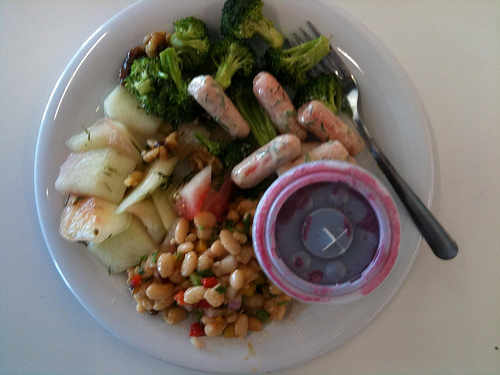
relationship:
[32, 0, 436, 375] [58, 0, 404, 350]
plate has a meal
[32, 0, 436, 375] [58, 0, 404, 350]
plate has food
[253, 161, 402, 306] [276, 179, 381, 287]
container has sauce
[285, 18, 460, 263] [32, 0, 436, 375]
fork on plate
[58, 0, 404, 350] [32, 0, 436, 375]
meal on a plate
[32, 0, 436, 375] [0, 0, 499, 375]
plate on surface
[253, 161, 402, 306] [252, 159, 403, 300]
container has a lid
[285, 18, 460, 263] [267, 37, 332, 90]
fork under broccoli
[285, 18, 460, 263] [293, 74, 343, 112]
fork under broccoli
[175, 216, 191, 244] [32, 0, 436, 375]
bean on plate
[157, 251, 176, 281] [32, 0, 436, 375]
bean on plate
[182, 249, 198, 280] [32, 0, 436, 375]
bean on plate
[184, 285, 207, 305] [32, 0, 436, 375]
bean on plate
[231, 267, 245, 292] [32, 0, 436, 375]
bean on plate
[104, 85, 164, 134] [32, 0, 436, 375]
potato on plate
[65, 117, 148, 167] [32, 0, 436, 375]
potato on plate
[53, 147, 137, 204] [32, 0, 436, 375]
potato on plate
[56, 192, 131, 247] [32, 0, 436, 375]
potato on plate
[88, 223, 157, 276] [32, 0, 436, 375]
potato on plate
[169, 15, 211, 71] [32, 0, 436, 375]
broccoli on plate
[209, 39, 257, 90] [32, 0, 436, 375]
broccoli on plate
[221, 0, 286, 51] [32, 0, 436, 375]
broccoli on plate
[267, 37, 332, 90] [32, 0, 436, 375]
broccoli on plate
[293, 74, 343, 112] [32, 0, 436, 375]
broccoli on plate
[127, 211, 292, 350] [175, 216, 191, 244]
salad has a bean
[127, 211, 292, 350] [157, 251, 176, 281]
salad has a bean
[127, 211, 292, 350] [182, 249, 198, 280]
salad has a bean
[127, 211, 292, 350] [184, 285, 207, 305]
salad has a bean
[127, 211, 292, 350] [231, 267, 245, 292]
salad has a bean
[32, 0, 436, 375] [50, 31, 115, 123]
plate has a reflection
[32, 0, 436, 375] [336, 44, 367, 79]
plate has a reflection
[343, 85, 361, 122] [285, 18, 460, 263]
reflection on fork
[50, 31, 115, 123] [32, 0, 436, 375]
reflection on plate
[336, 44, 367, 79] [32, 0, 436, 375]
reflection on plate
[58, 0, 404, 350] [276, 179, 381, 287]
meal has a sauce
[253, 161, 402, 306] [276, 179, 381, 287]
container has a sauce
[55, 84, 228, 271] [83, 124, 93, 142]
salad has dill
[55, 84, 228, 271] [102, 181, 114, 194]
salad has dill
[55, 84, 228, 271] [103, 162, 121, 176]
salad has dill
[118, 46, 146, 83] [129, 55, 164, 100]
walnut by broccoli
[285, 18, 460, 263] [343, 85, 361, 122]
fork has a reflection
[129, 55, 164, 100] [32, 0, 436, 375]
broccoli on plate